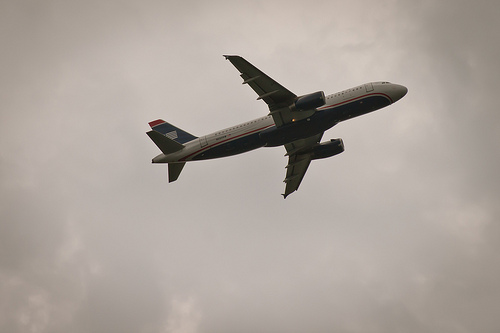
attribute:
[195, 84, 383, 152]
line — red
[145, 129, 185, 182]
small wings — small , flared 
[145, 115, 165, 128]
tip — red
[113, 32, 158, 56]
sky — gray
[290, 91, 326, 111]
engine — curved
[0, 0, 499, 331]
sky — gray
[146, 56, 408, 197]
plane — flying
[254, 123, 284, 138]
cylinder — pointed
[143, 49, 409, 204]
plane — flying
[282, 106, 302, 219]
light — small and yellow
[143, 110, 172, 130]
tip — red